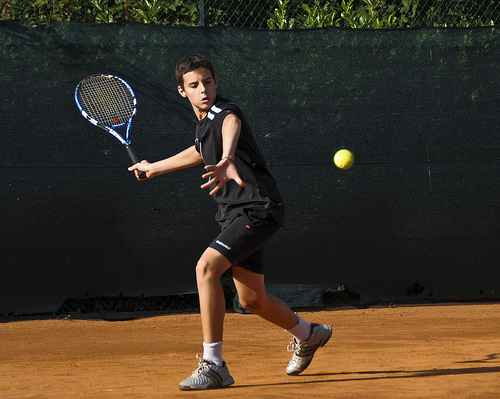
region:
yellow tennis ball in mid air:
[322, 140, 367, 173]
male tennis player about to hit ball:
[64, 33, 343, 398]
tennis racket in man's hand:
[60, 61, 160, 184]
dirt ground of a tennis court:
[10, 329, 178, 392]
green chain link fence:
[196, 2, 493, 23]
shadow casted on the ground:
[316, 358, 496, 383]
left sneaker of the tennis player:
[175, 348, 240, 396]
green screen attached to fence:
[281, 38, 483, 130]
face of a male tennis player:
[164, 52, 238, 117]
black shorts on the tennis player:
[197, 203, 302, 289]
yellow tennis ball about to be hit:
[328, 147, 360, 172]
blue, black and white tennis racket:
[69, 69, 149, 185]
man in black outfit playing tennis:
[128, 53, 332, 391]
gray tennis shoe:
[179, 333, 236, 390]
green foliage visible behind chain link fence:
[1, 0, 499, 30]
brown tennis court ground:
[4, 310, 497, 397]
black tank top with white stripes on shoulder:
[185, 99, 281, 216]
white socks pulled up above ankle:
[196, 337, 226, 363]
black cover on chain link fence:
[2, 22, 496, 298]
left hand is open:
[197, 150, 244, 197]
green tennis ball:
[326, 145, 357, 170]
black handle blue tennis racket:
[65, 71, 148, 183]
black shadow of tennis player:
[229, 345, 499, 386]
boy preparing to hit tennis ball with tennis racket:
[57, 47, 358, 395]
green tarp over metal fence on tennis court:
[1, 19, 496, 304]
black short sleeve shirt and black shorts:
[190, 108, 287, 276]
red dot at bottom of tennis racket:
[108, 112, 121, 124]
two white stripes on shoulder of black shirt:
[206, 103, 225, 122]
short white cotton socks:
[197, 338, 226, 363]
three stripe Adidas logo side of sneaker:
[200, 367, 225, 385]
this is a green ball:
[320, 136, 372, 182]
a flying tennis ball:
[305, 117, 392, 214]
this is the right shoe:
[268, 309, 351, 381]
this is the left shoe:
[143, 328, 252, 397]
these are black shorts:
[198, 190, 301, 280]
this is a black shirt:
[166, 73, 306, 245]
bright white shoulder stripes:
[206, 99, 225, 122]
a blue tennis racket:
[54, 25, 187, 238]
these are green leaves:
[289, 5, 343, 29]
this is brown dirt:
[383, 309, 454, 374]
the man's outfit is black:
[142, 105, 372, 330]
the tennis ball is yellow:
[320, 125, 362, 185]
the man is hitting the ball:
[56, 50, 352, 262]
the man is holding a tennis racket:
[62, 41, 353, 253]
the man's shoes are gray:
[163, 310, 361, 397]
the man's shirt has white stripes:
[193, 97, 238, 136]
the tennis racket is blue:
[55, 70, 155, 192]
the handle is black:
[113, 139, 153, 186]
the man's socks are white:
[150, 280, 350, 387]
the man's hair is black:
[162, 46, 272, 105]